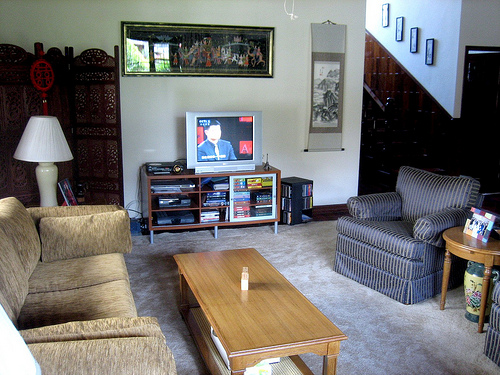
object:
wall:
[111, 0, 313, 193]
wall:
[380, 0, 459, 116]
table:
[180, 248, 343, 353]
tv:
[185, 111, 262, 174]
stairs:
[364, 74, 421, 176]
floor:
[282, 234, 396, 350]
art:
[303, 21, 346, 153]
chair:
[333, 166, 479, 306]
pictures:
[425, 38, 435, 65]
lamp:
[14, 115, 73, 208]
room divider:
[35, 37, 121, 201]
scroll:
[304, 20, 345, 155]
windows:
[122, 36, 169, 72]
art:
[121, 21, 274, 77]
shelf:
[190, 296, 235, 375]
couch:
[0, 197, 178, 375]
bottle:
[240, 266, 249, 290]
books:
[235, 191, 251, 218]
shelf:
[234, 191, 273, 204]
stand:
[137, 163, 282, 246]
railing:
[361, 89, 398, 169]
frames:
[425, 39, 428, 64]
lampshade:
[15, 115, 74, 162]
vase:
[464, 261, 493, 323]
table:
[455, 223, 498, 251]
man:
[197, 120, 237, 162]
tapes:
[208, 192, 227, 195]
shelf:
[201, 206, 230, 211]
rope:
[284, 3, 298, 21]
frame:
[120, 21, 127, 76]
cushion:
[37, 211, 132, 261]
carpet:
[138, 240, 185, 346]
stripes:
[412, 178, 448, 192]